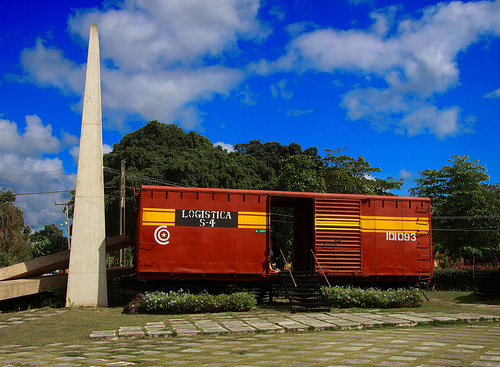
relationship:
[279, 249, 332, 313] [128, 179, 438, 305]
stairs in boxcar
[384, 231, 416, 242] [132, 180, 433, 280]
101093 on boxcar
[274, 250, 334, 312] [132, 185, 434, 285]
stairs on boxcar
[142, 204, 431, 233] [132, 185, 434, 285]
stripes on boxcar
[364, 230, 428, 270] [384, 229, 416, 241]
background on lettering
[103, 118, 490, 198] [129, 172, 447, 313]
trees behind train car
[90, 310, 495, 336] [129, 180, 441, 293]
pathway in front of train car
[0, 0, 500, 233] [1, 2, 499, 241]
clouds in sky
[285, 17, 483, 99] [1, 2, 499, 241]
clouds in sky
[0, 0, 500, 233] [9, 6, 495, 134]
clouds in sky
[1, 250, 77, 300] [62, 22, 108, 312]
slabs near pointy monument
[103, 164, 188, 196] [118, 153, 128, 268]
wires on pole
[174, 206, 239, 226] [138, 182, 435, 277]
logo side boxcar side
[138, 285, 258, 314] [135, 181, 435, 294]
bushes next boxcar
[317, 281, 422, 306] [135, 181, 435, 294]
bushes next boxcar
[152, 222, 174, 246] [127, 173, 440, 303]
target spot on trailer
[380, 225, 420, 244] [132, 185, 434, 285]
101093 on boxcar